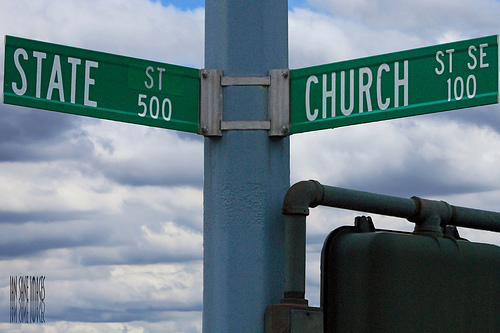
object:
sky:
[1, 0, 499, 331]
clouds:
[2, 0, 500, 331]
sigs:
[3, 34, 498, 136]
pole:
[204, 1, 289, 331]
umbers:
[357, 249, 499, 328]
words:
[10, 47, 101, 108]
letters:
[305, 60, 408, 119]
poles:
[263, 179, 498, 331]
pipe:
[283, 179, 498, 332]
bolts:
[198, 68, 290, 139]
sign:
[3, 34, 199, 134]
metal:
[201, 70, 291, 135]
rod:
[283, 216, 305, 296]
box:
[321, 216, 499, 330]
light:
[1, 0, 204, 33]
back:
[320, 216, 500, 332]